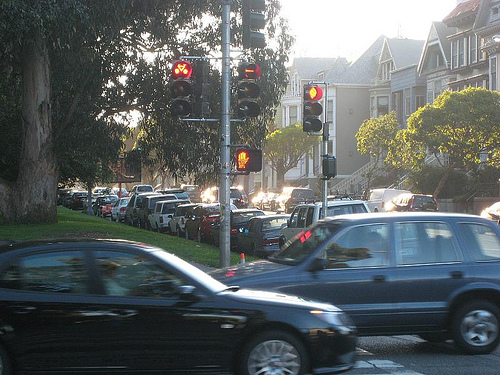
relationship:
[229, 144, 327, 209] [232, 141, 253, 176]
signal showing hand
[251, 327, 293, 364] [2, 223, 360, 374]
wheel on car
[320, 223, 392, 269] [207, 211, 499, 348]
window on vehicle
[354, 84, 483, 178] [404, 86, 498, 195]
leaves on tree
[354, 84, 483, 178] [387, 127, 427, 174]
leaves on tree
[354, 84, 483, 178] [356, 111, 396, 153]
leaves on tree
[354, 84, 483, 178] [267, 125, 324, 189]
leaves on tree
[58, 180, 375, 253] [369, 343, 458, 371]
parked cars on road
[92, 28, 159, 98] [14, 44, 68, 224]
leaves on tree trunk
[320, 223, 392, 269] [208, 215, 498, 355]
window of car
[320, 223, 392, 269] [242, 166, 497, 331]
window of a car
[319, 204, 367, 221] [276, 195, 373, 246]
window of a car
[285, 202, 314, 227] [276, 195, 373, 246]
window of car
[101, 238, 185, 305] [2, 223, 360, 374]
window of car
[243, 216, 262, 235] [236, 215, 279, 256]
window of car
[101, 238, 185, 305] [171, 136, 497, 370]
window of car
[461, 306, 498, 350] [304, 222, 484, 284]
wheel of vehicle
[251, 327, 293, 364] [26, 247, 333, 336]
wheel of vehicle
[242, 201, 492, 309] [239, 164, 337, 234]
car on street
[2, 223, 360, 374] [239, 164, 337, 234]
car on street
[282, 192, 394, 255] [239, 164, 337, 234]
car on street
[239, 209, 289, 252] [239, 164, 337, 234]
car on street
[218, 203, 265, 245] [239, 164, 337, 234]
car on street